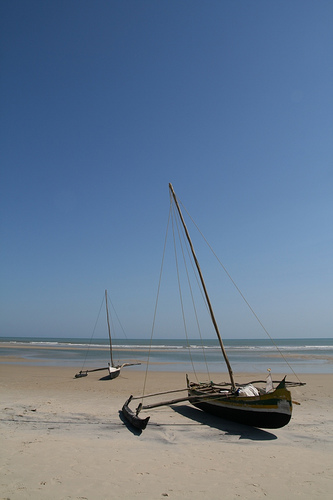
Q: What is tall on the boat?
A: A mast.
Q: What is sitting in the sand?
A: Boats.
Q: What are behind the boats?
A: The ocean.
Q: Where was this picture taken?
A: At the beach.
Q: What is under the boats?
A: Sand.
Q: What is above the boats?
A: The sky.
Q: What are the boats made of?
A: Wood.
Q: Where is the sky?
A: Above the boats.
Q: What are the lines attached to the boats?
A: Sail lines.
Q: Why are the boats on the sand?
A: They are docked.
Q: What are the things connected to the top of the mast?
A: Long ropes.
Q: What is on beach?
A: Two boats.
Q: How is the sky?
A: Clear.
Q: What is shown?
A: Sailboats.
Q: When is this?
A: During the day.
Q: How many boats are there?
A: Two.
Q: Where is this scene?
A: The beach.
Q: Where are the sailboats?
A: On the sand.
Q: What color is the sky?
A: Blue.